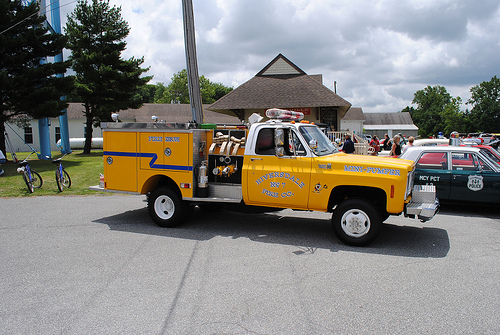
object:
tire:
[145, 185, 188, 228]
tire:
[329, 195, 382, 245]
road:
[1, 193, 499, 334]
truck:
[99, 106, 438, 248]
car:
[391, 145, 499, 211]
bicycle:
[48, 154, 71, 194]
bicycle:
[17, 154, 44, 195]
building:
[363, 112, 419, 143]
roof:
[362, 111, 413, 123]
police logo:
[465, 173, 485, 191]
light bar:
[265, 106, 306, 120]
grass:
[1, 149, 105, 197]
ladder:
[180, 0, 205, 126]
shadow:
[91, 205, 449, 259]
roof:
[204, 52, 350, 112]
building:
[204, 53, 350, 132]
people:
[338, 133, 417, 158]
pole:
[50, 0, 74, 156]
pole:
[35, 0, 53, 157]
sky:
[0, 0, 499, 113]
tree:
[59, 0, 157, 154]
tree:
[1, 0, 78, 163]